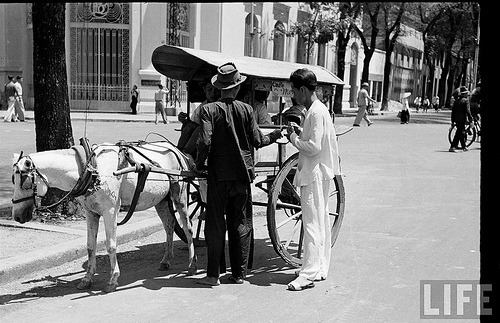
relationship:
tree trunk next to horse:
[20, 4, 82, 209] [12, 139, 209, 292]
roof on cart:
[151, 42, 344, 87] [147, 42, 345, 271]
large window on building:
[67, 0, 132, 112] [1, 0, 478, 110]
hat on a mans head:
[211, 61, 248, 89] [204, 64, 246, 103]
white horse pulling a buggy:
[9, 137, 203, 292] [150, 42, 353, 271]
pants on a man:
[205, 159, 256, 303] [180, 54, 275, 291]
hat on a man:
[211, 61, 248, 89] [192, 62, 282, 284]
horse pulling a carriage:
[12, 139, 209, 292] [155, 33, 347, 265]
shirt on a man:
[183, 87, 270, 196] [184, 60, 274, 283]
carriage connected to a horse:
[146, 42, 351, 274] [5, 130, 197, 275]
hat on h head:
[211, 61, 248, 89] [212, 67, 242, 96]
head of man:
[212, 67, 242, 96] [180, 83, 284, 267]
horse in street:
[12, 139, 209, 292] [1, 108, 481, 321]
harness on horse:
[11, 138, 204, 215] [3, 130, 212, 299]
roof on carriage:
[151, 42, 344, 87] [134, 40, 372, 294]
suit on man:
[197, 102, 262, 269] [197, 67, 271, 281]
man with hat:
[197, 67, 271, 281] [208, 60, 246, 94]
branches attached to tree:
[353, 7, 378, 52] [291, 0, 381, 101]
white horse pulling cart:
[9, 137, 203, 292] [147, 42, 345, 271]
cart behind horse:
[147, 42, 345, 271] [12, 139, 209, 292]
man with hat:
[280, 69, 340, 293] [207, 59, 247, 90]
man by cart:
[280, 69, 340, 293] [147, 42, 345, 271]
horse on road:
[12, 139, 209, 292] [351, 154, 454, 287]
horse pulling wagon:
[12, 139, 209, 292] [142, 31, 352, 278]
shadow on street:
[86, 216, 310, 301] [1, 108, 481, 321]